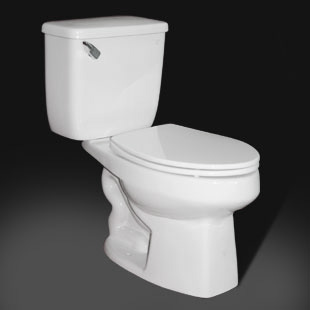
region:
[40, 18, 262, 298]
a white toilet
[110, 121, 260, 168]
a plastic toilet seat lid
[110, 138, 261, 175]
a plastic toilet seat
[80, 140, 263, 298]
a toilet bowl basin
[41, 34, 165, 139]
a white porcelain toilet tank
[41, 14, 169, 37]
a white toilet tank lid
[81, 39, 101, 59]
a chrome flush handle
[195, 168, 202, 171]
a white lid spacer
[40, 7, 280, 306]
white ceramic toilet bowl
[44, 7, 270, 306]
white ceramic toilet bowl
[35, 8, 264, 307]
white ceramic toilet bowl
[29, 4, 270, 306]
white ceramic toilet bowl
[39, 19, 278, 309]
white ceramic toilet bowl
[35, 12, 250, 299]
white ceramic toilet bowl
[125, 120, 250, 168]
lid of the toilet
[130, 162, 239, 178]
seat of the toilet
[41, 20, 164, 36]
tank of the toilet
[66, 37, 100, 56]
button of the toilet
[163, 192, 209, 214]
he toilet is porcelain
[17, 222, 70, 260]
the floor is gray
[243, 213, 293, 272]
shadow of the toilet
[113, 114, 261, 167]
toilet seat lid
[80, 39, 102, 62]
silver handle to flush the toilet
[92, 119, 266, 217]
large white toilet bowl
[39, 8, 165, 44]
top of the toilet tank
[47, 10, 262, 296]
a white new toilet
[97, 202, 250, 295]
base of the toilet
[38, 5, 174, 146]
the toilet tank behind the toilet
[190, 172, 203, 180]
protective pad on the toilet seat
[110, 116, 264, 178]
a white unused toilet seat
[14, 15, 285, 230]
toilet in the photo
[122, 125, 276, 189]
white toilet on floor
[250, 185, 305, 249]
shadow on the ground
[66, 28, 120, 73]
handle on the toilet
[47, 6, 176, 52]
top part of toilet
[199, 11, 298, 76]
black background of photo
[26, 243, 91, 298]
light on the ground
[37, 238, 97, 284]
gray floor under toilet